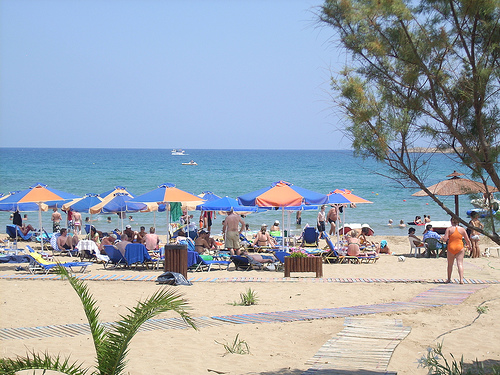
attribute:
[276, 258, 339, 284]
trash — brown, wood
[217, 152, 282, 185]
water — blue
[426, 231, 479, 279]
woman — walking